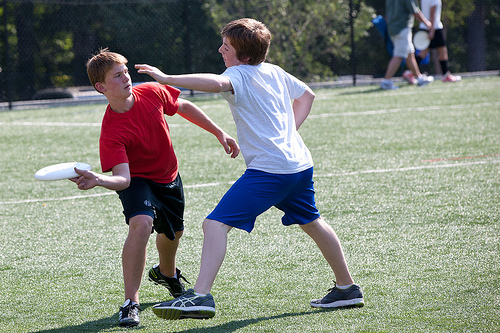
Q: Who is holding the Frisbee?
A: The boy on the left.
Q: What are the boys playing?
A: Frisbee.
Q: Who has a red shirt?
A: The boy on the left.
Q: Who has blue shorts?
A: The boy on the right.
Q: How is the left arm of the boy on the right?
A: Extended.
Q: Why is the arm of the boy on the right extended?
A: To block the Frisbee.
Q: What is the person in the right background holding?
A: A white Frisbee.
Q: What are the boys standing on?
A: A field.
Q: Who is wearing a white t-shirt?
A: The boy on the right.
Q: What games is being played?
A: Frisbee.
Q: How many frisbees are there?
A: Two.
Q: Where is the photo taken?
A: Field.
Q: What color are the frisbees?
A: White.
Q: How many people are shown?
A: Four.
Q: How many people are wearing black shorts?
A: Two.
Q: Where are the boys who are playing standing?
A: On grass.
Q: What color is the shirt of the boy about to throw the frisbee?
A: Red.